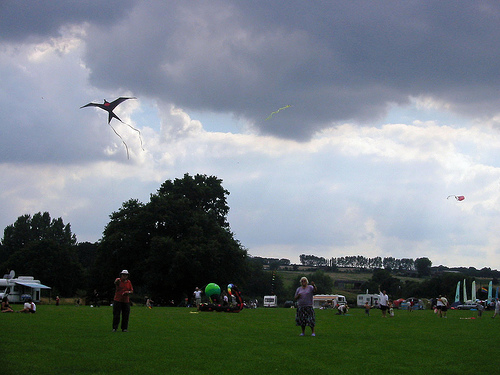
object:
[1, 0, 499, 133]
clouds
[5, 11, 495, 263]
sky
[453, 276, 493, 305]
wall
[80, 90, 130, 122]
bird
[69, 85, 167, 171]
kite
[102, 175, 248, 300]
trees